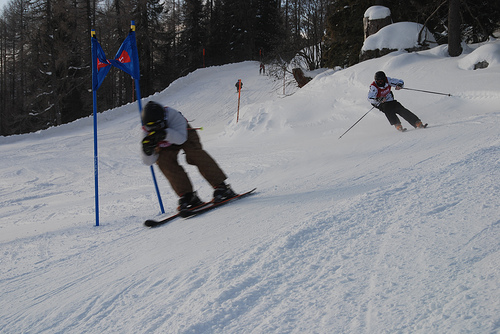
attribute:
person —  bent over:
[136, 94, 247, 209]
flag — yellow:
[58, 28, 118, 256]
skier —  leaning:
[369, 71, 424, 131]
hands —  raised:
[132, 127, 177, 155]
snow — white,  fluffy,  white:
[3, 40, 489, 322]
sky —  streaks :
[0, 0, 325, 60]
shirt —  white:
[158, 104, 185, 148]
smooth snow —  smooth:
[234, 68, 490, 163]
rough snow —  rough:
[207, 142, 498, 332]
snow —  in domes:
[363, 5, 390, 21]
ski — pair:
[143, 202, 191, 229]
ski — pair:
[181, 186, 256, 216]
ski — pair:
[395, 127, 407, 134]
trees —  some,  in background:
[0, 0, 281, 58]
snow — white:
[310, 189, 443, 319]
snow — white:
[280, 179, 403, 268]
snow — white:
[299, 141, 476, 267]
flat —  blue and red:
[72, 28, 217, 222]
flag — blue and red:
[110, 23, 144, 83]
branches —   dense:
[1, 7, 283, 132]